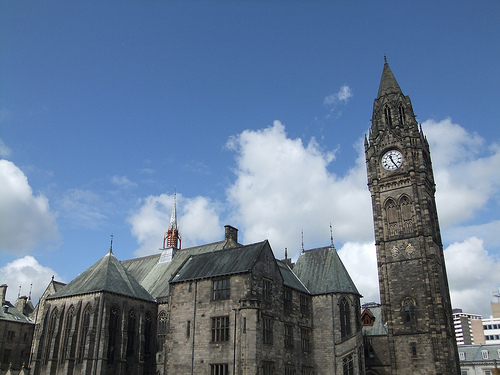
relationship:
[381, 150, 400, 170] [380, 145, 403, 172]
roman numbers on clock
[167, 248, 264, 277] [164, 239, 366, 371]
roof on building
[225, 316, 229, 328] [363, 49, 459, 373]
window on building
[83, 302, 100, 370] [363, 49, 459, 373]
window on building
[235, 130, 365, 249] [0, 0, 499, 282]
clouds patch in sky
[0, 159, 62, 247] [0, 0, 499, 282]
cloud in sky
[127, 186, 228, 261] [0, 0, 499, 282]
cloud in sky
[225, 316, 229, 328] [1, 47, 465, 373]
window on building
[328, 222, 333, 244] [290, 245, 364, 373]
antenae on building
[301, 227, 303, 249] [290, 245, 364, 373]
antenae on building